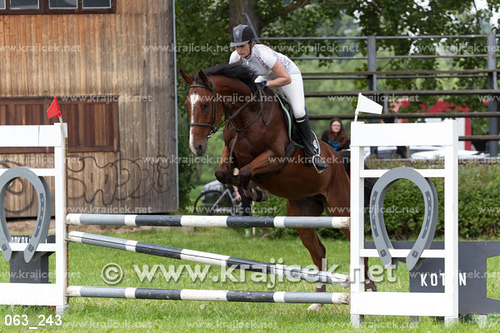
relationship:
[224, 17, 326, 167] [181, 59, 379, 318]
man racing horse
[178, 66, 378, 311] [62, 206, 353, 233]
horse jumping poles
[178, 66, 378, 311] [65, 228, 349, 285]
horse jumping poles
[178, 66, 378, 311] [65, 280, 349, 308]
horse jumping poles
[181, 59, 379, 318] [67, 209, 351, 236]
horse jumping pole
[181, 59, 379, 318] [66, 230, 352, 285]
horse jumping pole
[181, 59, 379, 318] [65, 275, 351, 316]
horse jumping pole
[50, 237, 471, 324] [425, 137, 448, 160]
grass on ground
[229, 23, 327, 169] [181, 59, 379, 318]
man on horse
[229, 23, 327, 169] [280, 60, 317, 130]
man wearing pants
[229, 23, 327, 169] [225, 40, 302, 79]
man wearing shirt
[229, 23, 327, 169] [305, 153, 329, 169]
man wearing boot